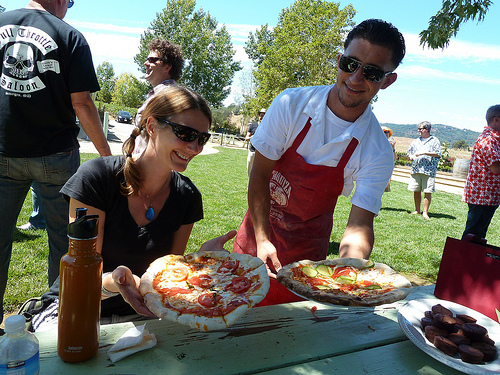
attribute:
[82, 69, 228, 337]
woman — holding, wearing, wear, hold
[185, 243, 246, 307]
pizza — sauce, tomato, cheese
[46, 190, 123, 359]
container — tall, sitting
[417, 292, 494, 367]
brownies — plate, full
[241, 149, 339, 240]
apron — red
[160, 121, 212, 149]
glass — sun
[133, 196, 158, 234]
gem — blue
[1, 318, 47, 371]
water — bottle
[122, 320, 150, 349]
napkin — folded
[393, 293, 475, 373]
plate — dessert, white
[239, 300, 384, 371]
table — picnic, picic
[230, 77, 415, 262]
man — wearing, wear, hold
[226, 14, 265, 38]
sky — blue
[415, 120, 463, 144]
mountains — back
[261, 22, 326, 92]
tree — leaves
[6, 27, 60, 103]
shirt — black